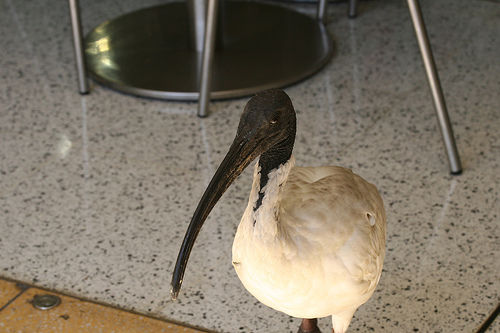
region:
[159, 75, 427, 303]
this is a bird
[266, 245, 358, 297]
the bird is white in color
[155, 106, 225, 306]
this is a beak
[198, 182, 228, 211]
the beak is black in color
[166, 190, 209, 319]
the beak is long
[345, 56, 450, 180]
this is the floor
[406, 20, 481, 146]
this is a pole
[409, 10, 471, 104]
this is a metal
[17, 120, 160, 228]
the floor is shinny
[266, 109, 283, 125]
this is the eye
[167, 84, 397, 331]
large black and white bird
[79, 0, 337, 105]
circular silver metal table base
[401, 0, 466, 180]
silver metal chair leg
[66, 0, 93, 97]
silver metal chair leg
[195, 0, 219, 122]
silver metal chair leg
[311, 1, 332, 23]
silver metal chair leg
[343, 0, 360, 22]
silver metal chair leg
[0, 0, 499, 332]
gray white and black speckled floor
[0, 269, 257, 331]
yellow stone floor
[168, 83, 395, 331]
large white bird with black head and beak standing on hard floor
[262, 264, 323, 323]
part of a chest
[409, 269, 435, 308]
[part of a wall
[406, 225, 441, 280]
part of a glass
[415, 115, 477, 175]
part of a stand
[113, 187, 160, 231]
part of a glass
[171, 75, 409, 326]
this is a bird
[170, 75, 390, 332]
the bird is standing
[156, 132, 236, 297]
this is a beak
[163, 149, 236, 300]
the beak is long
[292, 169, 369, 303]
the feathers are folded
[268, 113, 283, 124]
this is the eye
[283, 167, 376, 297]
the feathers is white in color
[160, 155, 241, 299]
the beak is curved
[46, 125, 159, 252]
the floor is tiled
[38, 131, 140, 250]
the floor is white in color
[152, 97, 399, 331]
white and black bird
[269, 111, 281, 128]
eye on the side of the head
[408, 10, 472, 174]
silver leg of a chair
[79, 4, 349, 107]
round silver base of a table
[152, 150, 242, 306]
long black beak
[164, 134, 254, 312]
beak is sloped downwards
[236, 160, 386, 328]
body of the bird is white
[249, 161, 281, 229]
white and black neck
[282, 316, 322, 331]
the bird's foot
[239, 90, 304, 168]
head is black